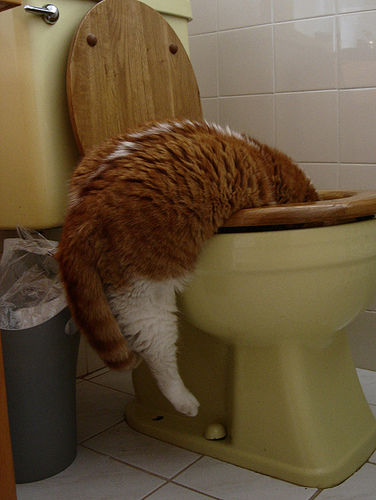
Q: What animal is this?
A: A cat.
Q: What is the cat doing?
A: Drinking from the toilet.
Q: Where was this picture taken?
A: A bathroom.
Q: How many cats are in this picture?
A: 1.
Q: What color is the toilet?
A: Yellow.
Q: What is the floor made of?
A: Tile.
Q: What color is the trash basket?
A: Gray.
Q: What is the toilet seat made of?
A: Wood.